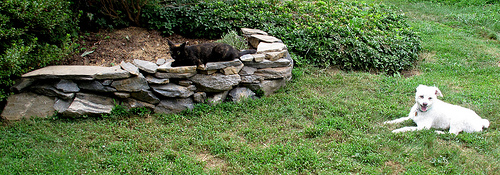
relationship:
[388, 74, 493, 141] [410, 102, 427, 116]
dog with collar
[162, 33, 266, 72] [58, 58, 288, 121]
cat on rocks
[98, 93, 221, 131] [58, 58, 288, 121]
grass by rocks